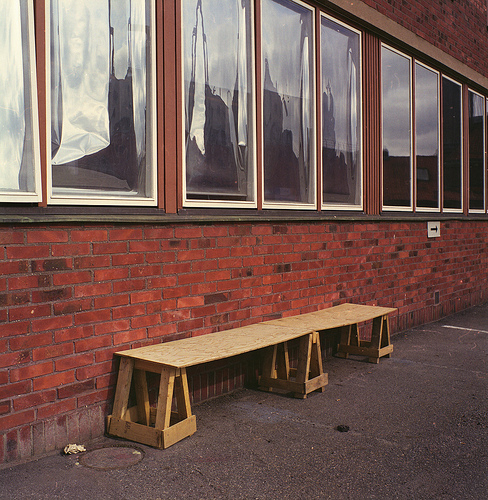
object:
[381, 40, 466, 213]
window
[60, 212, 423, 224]
ledge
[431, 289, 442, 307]
vent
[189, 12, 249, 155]
curtain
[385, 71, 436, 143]
sky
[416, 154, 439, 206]
building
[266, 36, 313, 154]
curtain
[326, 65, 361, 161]
curtain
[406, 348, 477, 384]
crack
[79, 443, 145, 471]
cover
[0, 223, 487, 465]
wall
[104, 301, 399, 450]
bench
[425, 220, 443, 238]
sign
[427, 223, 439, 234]
arrow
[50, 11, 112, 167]
curtain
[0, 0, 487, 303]
building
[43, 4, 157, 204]
window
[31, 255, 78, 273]
brick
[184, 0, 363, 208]
window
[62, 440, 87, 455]
trash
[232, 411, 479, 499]
concrete